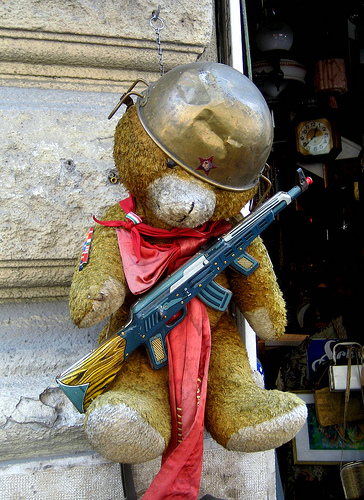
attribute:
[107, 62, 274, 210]
pot — old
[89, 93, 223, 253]
bear — stuffed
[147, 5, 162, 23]
hook — metal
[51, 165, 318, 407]
rifle — toy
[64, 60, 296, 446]
bear — stuffed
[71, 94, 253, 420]
bear — stuffed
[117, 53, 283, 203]
pan — metal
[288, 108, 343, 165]
clock — old, wooden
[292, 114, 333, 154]
hands — black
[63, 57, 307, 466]
bear — stuffed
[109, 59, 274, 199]
pan — metal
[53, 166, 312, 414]
toy gun — wood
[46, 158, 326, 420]
gun — toy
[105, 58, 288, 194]
pot — metal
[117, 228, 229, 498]
scarf — red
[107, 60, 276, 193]
bowl — battered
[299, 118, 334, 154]
clock — white, brown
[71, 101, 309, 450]
bear — stuffed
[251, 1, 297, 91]
lamp — sconce, wall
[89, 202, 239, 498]
scarf — red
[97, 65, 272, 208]
helmet — military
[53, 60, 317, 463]
rifle — toy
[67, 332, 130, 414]
butt — wooden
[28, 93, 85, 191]
wall — stone